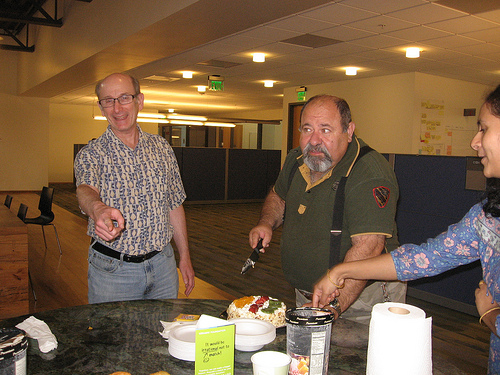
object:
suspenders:
[285, 146, 407, 302]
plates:
[162, 317, 234, 364]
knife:
[240, 245, 266, 275]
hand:
[248, 217, 273, 245]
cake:
[228, 293, 288, 328]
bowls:
[364, 301, 433, 373]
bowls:
[229, 316, 276, 351]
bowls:
[167, 322, 203, 359]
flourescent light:
[89, 114, 233, 129]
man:
[75, 73, 195, 303]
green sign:
[194, 323, 234, 374]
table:
[0, 300, 441, 374]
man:
[249, 94, 407, 325]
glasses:
[98, 88, 135, 106]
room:
[0, 0, 498, 373]